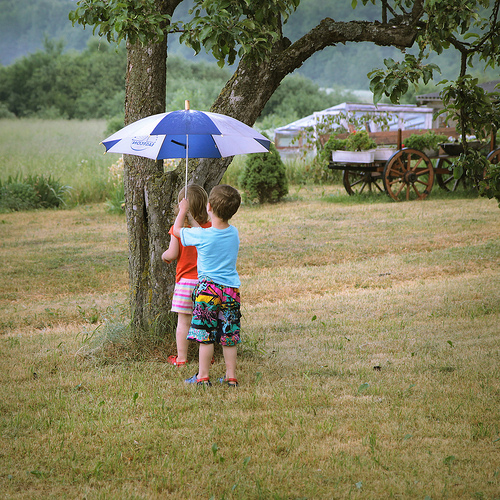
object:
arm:
[170, 197, 200, 246]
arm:
[159, 235, 183, 267]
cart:
[326, 120, 493, 201]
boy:
[173, 181, 242, 388]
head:
[206, 185, 242, 220]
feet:
[217, 375, 238, 386]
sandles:
[183, 372, 213, 387]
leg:
[174, 314, 192, 357]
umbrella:
[97, 100, 275, 164]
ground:
[17, 322, 475, 499]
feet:
[185, 372, 212, 387]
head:
[177, 182, 209, 226]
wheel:
[382, 147, 433, 202]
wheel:
[341, 156, 387, 196]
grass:
[1, 180, 498, 497]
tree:
[69, 0, 499, 351]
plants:
[344, 129, 370, 152]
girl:
[161, 182, 216, 365]